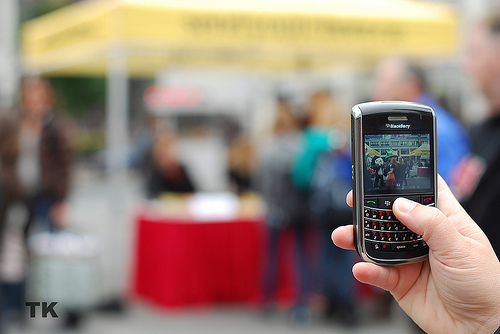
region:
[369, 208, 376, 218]
A red number on a phone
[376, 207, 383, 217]
A red number on a phone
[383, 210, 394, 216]
A red number on a phone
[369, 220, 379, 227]
A red number on a phone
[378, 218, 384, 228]
A red number on a phone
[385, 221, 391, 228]
A red number on a phone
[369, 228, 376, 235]
A red number on a phone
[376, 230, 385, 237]
A red number on a phone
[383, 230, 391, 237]
A red number on a phone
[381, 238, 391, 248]
A red number on a phone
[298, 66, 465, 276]
man holding a blackberry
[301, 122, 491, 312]
the man's right hand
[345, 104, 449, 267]
the phone taking a picture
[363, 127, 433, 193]
an image on the phone screen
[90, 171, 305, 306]
red table in the background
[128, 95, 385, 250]
group of people in the background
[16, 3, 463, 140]
a yellow pop-up tent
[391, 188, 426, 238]
the man's cut fingernail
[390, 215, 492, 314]
the man's hand wrinkles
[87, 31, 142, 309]
metal poles holding up the tent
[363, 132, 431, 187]
The screen of the Blackberry cellphone.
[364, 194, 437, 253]
The buttons on the phone.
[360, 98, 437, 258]
The phone in the person's hand.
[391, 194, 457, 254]
The person's thumb pressing the button.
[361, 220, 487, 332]
The palm of the person holding the phone.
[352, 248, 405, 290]
The pinky on the person's hand.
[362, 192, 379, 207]
The green button with the picture of a telephone on the cellphone.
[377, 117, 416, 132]
The white letters above the phone's screen.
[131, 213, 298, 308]
The red table in the background.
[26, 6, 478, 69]
The yellow canopy above the red table.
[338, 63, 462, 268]
A smartphone cell phone.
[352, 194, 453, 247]
A QWERTY keyboard on the cell phone for ease of typing.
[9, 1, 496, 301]
A very blurry background picture.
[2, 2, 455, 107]
A large yellow awning.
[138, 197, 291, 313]
A red table cloth.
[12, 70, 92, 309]
A person with a large bag.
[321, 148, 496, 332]
A persons hand.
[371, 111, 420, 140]
A Blackberry brand cell phone.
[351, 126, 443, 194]
A very clear picture on the cell phone.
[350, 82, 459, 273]
A black cell phone.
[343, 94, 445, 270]
black and silver blackberry with keypad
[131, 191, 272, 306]
blurry red and white cooler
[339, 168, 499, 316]
white hand holding a phone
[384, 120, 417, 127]
white logo on phone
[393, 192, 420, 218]
thumb fingernail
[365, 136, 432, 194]
smartphone screen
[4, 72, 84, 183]
blurry bystander in a brown coat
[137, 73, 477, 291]
taking a picture of the crowd with phone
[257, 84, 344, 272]
blurry line of people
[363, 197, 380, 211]
green phone icon button